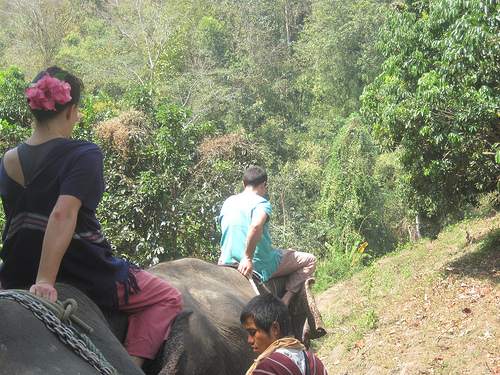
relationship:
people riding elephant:
[3, 67, 183, 365] [3, 256, 150, 373]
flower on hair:
[23, 73, 72, 113] [28, 67, 85, 122]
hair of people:
[28, 67, 85, 122] [3, 67, 183, 365]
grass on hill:
[312, 221, 497, 348] [307, 203, 498, 373]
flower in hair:
[23, 73, 72, 113] [23, 62, 83, 126]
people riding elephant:
[3, 67, 183, 365] [1, 279, 196, 374]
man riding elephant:
[217, 163, 319, 309] [137, 257, 327, 374]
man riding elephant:
[217, 163, 319, 309] [152, 257, 294, 366]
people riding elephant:
[3, 67, 183, 365] [8, 246, 275, 366]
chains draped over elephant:
[3, 287, 113, 372] [3, 256, 300, 373]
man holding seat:
[217, 163, 319, 309] [223, 257, 286, 302]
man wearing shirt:
[217, 163, 319, 309] [205, 181, 297, 279]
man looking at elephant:
[240, 293, 325, 373] [1, 279, 196, 374]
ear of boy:
[270, 321, 280, 334] [233, 290, 330, 373]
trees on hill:
[1, 4, 498, 271] [3, 2, 497, 292]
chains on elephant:
[3, 287, 113, 372] [137, 257, 327, 374]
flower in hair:
[23, 73, 72, 113] [29, 67, 79, 114]